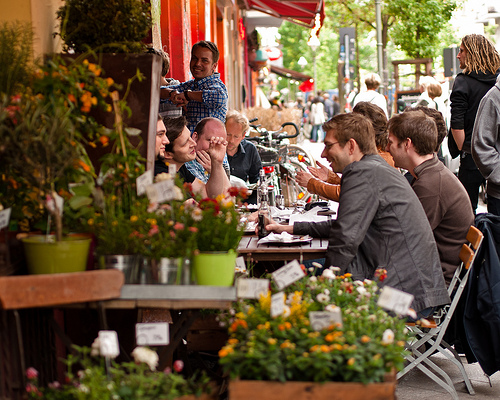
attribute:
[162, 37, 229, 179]
man — smiling, eating, enjoying meal, socializing, happy, looking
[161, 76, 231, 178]
shirt — blue, plaid, white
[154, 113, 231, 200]
person — eating, socializing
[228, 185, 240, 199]
flower — red, in area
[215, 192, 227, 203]
flower — yellow, in area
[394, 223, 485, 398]
chair — metal, wood, silver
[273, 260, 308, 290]
card — white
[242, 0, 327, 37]
awning — red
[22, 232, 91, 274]
flower pot — green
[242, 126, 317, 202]
bicycle — parked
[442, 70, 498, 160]
shirt — black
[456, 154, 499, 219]
pants — black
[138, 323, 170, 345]
sign — white, small, little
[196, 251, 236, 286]
flower pot — small, green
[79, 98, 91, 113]
flower — orange, in area, for sale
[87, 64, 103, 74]
flower — orange, in area, for sale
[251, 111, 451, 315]
man — sitting down, eating, enjoying meal, socializing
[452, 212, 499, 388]
jacket — blue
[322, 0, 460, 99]
tree — green, round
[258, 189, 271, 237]
bottle — clear, glass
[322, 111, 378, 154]
hair — light brown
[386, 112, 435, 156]
hair — light brown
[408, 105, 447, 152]
hair — light brown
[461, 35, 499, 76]
hair — dread locks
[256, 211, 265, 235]
label — black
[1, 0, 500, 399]
scene — busy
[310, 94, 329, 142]
person — in distance